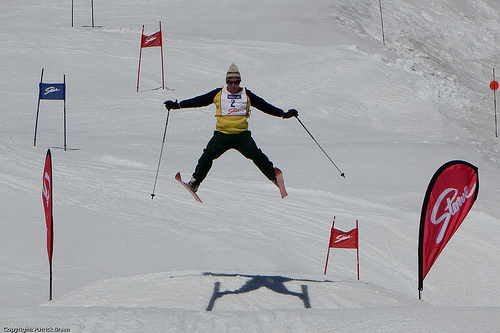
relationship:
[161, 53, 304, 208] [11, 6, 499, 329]
man in air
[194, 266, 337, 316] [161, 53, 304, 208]
shadow of man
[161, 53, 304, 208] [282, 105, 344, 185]
man has ski pole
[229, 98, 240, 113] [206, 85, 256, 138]
number on shirt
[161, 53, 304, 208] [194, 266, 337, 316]
man casting shadow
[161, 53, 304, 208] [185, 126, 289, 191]
man wearing pants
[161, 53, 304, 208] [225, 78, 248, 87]
man wearing sunglasses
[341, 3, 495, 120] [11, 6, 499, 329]
snow on ground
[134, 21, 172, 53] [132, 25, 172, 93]
flag on poles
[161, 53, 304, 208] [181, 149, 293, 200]
man has legs spread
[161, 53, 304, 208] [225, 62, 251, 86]
man wearing cap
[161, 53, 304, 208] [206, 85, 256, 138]
man wearing yellow shirt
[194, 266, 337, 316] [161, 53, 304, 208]
shadow of a man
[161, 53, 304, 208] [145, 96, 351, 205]
man has poles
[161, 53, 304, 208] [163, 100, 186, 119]
man wearing a glove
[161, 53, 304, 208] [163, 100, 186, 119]
man wearing glove on right hand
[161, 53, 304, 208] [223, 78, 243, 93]
man has face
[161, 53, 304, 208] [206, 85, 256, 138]
man wearing a yellow shirt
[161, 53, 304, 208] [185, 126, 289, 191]
man wearing black pants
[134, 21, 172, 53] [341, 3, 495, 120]
flag in snow